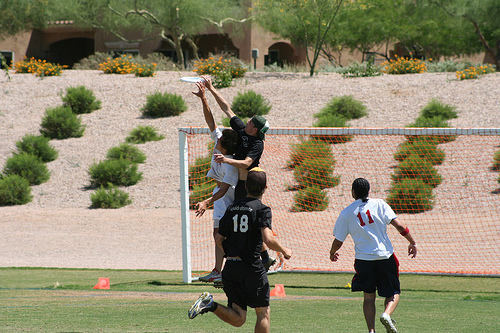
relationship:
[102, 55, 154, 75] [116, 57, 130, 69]
bush has flowers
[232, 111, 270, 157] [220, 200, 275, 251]
man wearing shirt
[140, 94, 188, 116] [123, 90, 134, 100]
bush on ground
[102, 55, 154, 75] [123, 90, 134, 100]
bush on ground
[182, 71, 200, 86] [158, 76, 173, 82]
frisbee in air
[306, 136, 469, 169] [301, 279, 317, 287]
net on field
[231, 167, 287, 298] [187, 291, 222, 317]
man has shoe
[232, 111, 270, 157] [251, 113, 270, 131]
man has hat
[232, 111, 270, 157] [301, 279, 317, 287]
man on field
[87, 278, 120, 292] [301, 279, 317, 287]
cone on field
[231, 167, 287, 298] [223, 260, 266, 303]
man has shorts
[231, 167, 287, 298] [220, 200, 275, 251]
man has shirt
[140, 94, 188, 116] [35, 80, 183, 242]
bush on hill